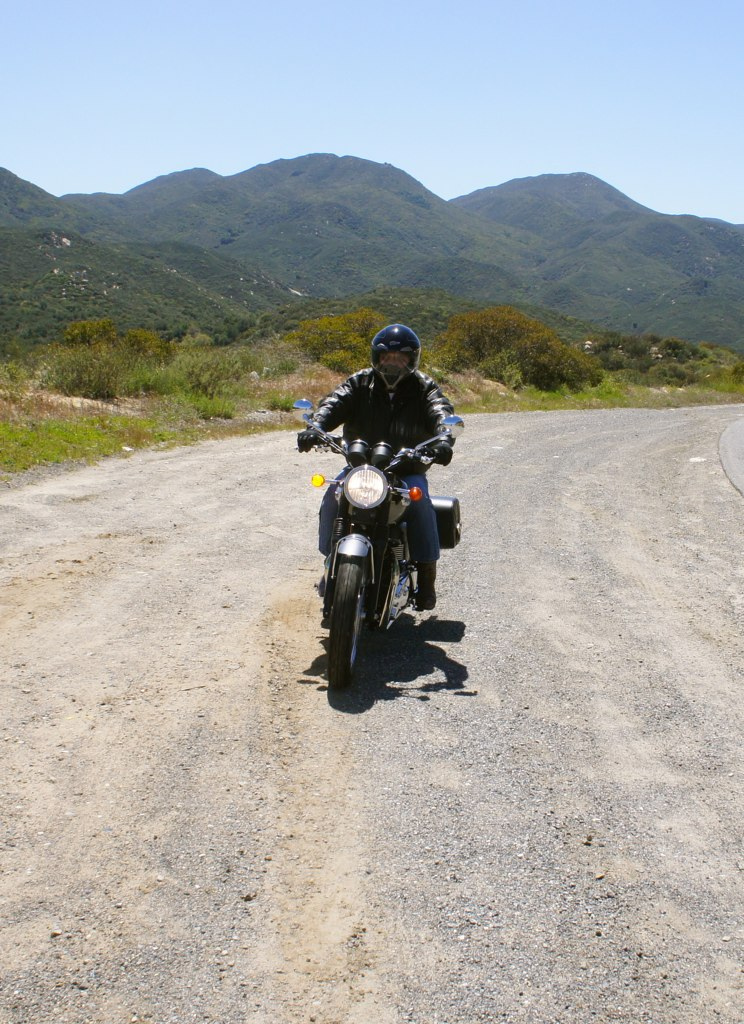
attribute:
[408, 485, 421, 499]
light — red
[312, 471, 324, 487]
light — yellow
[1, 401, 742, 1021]
path — dirt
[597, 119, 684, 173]
clouds — white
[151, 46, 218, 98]
clouds — white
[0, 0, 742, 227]
sky — blue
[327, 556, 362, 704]
tire — black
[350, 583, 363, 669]
wheel — silver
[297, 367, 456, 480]
jacket — black, shiny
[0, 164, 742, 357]
mountains — green, steep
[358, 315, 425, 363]
motorcycle helmet — black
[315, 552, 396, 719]
wheel — round, black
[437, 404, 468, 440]
rearview mirror — small, gray, metal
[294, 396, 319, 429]
rearview mirror —  metal, small, gray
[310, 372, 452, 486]
jacket — leather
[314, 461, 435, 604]
jeans — blue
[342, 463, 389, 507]
light — round, bright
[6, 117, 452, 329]
mountain — large 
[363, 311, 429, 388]
motorcycle helmet — black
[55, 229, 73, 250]
rock — piece, bare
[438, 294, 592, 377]
bush — thick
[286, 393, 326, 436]
mirror — metallic, side, reflecting light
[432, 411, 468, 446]
mirror — motorbike, side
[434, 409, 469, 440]
surface — metallic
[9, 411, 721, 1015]
road — gray, gravel, paved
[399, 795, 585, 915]
gravel — loose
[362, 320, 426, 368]
helmet — safety